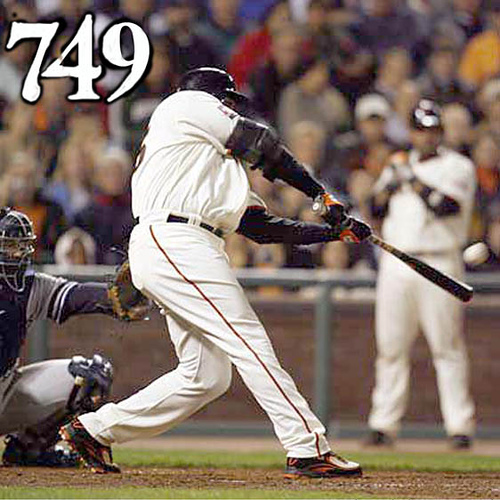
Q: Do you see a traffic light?
A: No, there are no traffic lights.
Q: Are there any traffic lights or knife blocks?
A: No, there are no traffic lights or knife blocks.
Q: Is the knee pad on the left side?
A: Yes, the knee pad is on the left of the image.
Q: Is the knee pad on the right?
A: No, the knee pad is on the left of the image.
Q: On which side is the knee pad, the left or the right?
A: The knee pad is on the left of the image.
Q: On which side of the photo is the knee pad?
A: The knee pad is on the left of the image.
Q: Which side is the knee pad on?
A: The knee pad is on the left of the image.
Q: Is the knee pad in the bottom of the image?
A: Yes, the knee pad is in the bottom of the image.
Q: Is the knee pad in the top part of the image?
A: No, the knee pad is in the bottom of the image.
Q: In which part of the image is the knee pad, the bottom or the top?
A: The knee pad is in the bottom of the image.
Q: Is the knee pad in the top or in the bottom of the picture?
A: The knee pad is in the bottom of the image.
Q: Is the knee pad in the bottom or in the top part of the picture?
A: The knee pad is in the bottom of the image.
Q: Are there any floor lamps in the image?
A: No, there are no floor lamps.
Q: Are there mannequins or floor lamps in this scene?
A: No, there are no floor lamps or mannequins.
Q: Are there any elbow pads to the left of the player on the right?
A: Yes, there is an elbow pad to the left of the player.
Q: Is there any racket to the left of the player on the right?
A: No, there is an elbow pad to the left of the player.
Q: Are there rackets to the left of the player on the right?
A: No, there is an elbow pad to the left of the player.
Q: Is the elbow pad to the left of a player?
A: Yes, the elbow pad is to the left of a player.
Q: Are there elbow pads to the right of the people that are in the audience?
A: Yes, there is an elbow pad to the right of the people.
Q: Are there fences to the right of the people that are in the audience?
A: No, there is an elbow pad to the right of the people.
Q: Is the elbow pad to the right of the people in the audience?
A: Yes, the elbow pad is to the right of the people.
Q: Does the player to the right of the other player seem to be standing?
A: Yes, the player is standing.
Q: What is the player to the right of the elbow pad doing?
A: The player is standing.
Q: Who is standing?
A: The player is standing.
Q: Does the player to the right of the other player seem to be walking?
A: No, the player is standing.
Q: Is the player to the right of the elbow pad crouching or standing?
A: The player is standing.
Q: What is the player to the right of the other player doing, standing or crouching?
A: The player is standing.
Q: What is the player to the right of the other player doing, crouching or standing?
A: The player is standing.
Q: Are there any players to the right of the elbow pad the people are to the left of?
A: Yes, there is a player to the right of the elbow pad.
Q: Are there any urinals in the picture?
A: No, there are no urinals.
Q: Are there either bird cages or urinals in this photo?
A: No, there are no urinals or bird cages.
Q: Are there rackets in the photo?
A: No, there are no rackets.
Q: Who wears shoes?
A: The player wears shoes.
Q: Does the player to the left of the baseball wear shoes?
A: Yes, the player wears shoes.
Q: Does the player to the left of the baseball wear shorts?
A: No, the player wears shoes.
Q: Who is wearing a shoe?
A: The player is wearing a shoe.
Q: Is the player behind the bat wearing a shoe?
A: Yes, the player is wearing a shoe.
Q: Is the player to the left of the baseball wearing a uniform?
A: No, the player is wearing a shoe.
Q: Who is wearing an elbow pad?
A: The player is wearing an elbow pad.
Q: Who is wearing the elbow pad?
A: The player is wearing an elbow pad.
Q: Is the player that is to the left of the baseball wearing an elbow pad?
A: Yes, the player is wearing an elbow pad.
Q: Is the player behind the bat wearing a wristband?
A: No, the player is wearing an elbow pad.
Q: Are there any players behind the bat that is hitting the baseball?
A: Yes, there is a player behind the bat.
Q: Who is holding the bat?
A: The player is holding the bat.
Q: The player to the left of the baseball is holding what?
A: The player is holding the bat.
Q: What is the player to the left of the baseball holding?
A: The player is holding the bat.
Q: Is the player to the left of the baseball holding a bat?
A: Yes, the player is holding a bat.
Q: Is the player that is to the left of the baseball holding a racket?
A: No, the player is holding a bat.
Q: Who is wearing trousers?
A: The player is wearing trousers.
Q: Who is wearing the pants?
A: The player is wearing trousers.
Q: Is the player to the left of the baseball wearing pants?
A: Yes, the player is wearing pants.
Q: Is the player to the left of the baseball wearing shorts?
A: No, the player is wearing pants.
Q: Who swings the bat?
A: The player swings the bat.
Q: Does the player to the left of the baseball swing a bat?
A: Yes, the player swings a bat.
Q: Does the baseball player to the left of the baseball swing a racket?
A: No, the player swings a bat.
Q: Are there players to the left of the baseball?
A: Yes, there is a player to the left of the baseball.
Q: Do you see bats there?
A: Yes, there is a bat.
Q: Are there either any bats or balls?
A: Yes, there is a bat.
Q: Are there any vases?
A: No, there are no vases.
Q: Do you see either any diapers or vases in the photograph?
A: No, there are no vases or diapers.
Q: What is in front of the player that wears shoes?
A: The bat is in front of the player.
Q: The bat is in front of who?
A: The bat is in front of the player.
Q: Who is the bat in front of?
A: The bat is in front of the player.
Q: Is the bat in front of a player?
A: Yes, the bat is in front of a player.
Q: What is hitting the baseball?
A: The bat is hitting the baseball.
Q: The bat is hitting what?
A: The bat is hitting the baseball.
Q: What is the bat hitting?
A: The bat is hitting the baseball.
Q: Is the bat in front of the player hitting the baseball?
A: Yes, the bat is hitting the baseball.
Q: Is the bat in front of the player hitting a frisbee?
A: No, the bat is hitting the baseball.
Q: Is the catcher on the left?
A: Yes, the catcher is on the left of the image.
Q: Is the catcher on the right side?
A: No, the catcher is on the left of the image.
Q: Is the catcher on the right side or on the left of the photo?
A: The catcher is on the left of the image.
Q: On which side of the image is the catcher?
A: The catcher is on the left of the image.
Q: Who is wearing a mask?
A: The catcher is wearing a mask.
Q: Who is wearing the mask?
A: The catcher is wearing a mask.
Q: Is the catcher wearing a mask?
A: Yes, the catcher is wearing a mask.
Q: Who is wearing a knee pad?
A: The catcher is wearing a knee pad.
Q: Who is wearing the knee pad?
A: The catcher is wearing a knee pad.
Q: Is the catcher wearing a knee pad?
A: Yes, the catcher is wearing a knee pad.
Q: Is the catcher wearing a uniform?
A: No, the catcher is wearing a knee pad.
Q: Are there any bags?
A: No, there are no bags.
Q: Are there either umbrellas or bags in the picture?
A: No, there are no bags or umbrellas.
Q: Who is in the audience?
A: The people are in the audience.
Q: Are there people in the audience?
A: Yes, there are people in the audience.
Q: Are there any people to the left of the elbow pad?
A: Yes, there are people to the left of the elbow pad.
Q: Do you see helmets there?
A: Yes, there is a helmet.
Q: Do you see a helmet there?
A: Yes, there is a helmet.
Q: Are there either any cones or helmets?
A: Yes, there is a helmet.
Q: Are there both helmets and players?
A: Yes, there are both a helmet and a player.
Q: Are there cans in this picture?
A: No, there are no cans.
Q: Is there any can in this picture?
A: No, there are no cans.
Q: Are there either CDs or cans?
A: No, there are no cans or cds.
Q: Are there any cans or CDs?
A: No, there are no cans or cds.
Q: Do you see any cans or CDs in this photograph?
A: No, there are no cans or cds.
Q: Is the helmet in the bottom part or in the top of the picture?
A: The helmet is in the top of the image.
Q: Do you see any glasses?
A: No, there are no glasses.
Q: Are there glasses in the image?
A: No, there are no glasses.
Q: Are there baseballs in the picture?
A: Yes, there is a baseball.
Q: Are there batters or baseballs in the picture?
A: Yes, there is a baseball.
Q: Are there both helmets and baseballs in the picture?
A: Yes, there are both a baseball and a helmet.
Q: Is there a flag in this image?
A: No, there are no flags.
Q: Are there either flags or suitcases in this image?
A: No, there are no flags or suitcases.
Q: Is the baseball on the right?
A: Yes, the baseball is on the right of the image.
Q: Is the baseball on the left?
A: No, the baseball is on the right of the image.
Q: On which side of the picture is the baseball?
A: The baseball is on the right of the image.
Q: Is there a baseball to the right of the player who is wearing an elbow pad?
A: Yes, there is a baseball to the right of the player.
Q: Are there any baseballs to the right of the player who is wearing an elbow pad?
A: Yes, there is a baseball to the right of the player.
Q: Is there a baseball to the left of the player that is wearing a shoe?
A: No, the baseball is to the right of the player.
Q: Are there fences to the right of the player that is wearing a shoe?
A: No, there is a baseball to the right of the player.